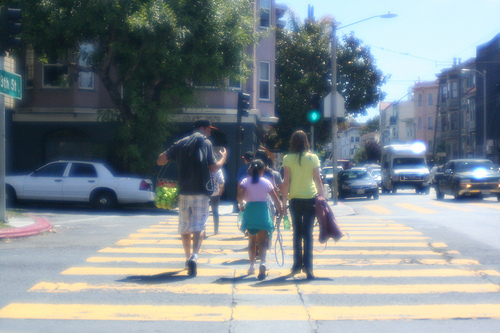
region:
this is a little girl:
[237, 160, 289, 282]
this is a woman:
[270, 120, 360, 298]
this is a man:
[149, 100, 234, 274]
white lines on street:
[30, 224, 495, 331]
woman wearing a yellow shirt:
[274, 130, 339, 223]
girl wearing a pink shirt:
[229, 173, 290, 209]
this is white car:
[10, 131, 164, 253]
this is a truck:
[432, 140, 497, 222]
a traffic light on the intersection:
[303, 87, 323, 123]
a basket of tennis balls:
[151, 162, 176, 207]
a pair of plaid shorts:
[177, 193, 208, 233]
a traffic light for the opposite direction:
[233, 85, 252, 160]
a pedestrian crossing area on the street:
[0, 276, 499, 332]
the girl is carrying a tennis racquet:
[273, 215, 285, 268]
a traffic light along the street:
[323, 9, 400, 204]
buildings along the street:
[341, 33, 499, 159]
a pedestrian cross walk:
[353, 201, 498, 217]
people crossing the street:
[159, 100, 343, 295]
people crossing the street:
[150, 105, 338, 279]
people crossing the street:
[156, 97, 333, 304]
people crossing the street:
[140, 102, 325, 296]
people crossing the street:
[122, 92, 343, 307]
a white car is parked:
[3, 136, 169, 219]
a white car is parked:
[8, 135, 166, 210]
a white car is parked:
[10, 133, 162, 228]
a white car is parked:
[3, 134, 169, 235]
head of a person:
[246, 156, 266, 178]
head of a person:
[287, 128, 325, 150]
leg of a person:
[170, 218, 224, 273]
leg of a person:
[235, 221, 283, 283]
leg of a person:
[286, 213, 326, 263]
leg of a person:
[200, 188, 237, 239]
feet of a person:
[182, 255, 213, 273]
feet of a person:
[240, 251, 282, 282]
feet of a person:
[282, 256, 332, 278]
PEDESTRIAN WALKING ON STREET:
[278, 127, 338, 284]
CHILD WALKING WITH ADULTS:
[231, 157, 276, 278]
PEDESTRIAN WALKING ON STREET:
[159, 117, 224, 283]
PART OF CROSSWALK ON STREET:
[358, 222, 404, 294]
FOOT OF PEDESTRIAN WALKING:
[186, 254, 201, 278]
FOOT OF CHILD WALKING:
[256, 263, 271, 284]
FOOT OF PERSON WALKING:
[301, 265, 323, 282]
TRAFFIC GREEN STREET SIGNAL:
[301, 85, 324, 127]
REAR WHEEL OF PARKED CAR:
[85, 186, 122, 211]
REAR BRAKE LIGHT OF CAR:
[137, 179, 152, 191]